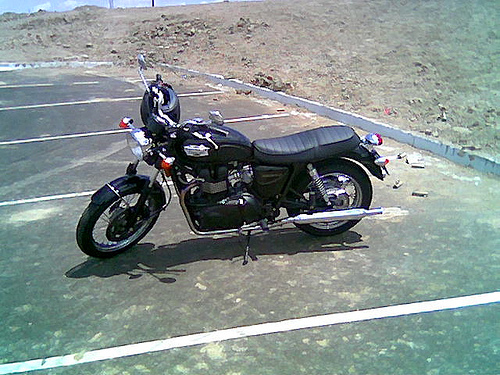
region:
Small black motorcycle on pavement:
[65, 41, 400, 284]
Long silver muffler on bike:
[283, 204, 415, 236]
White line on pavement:
[7, 331, 276, 372]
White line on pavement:
[255, 276, 461, 373]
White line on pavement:
[0, 188, 95, 212]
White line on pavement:
[3, 124, 128, 153]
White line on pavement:
[5, 101, 130, 136]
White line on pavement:
[5, 71, 127, 98]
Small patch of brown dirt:
[460, 97, 496, 155]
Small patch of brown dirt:
[394, 59, 484, 153]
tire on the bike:
[73, 172, 166, 259]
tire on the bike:
[285, 160, 375, 231]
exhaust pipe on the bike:
[197, 205, 402, 221]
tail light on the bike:
[360, 129, 384, 149]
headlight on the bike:
[120, 129, 147, 163]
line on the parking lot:
[2, 74, 173, 91]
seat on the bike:
[247, 120, 357, 157]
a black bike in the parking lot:
[70, 53, 393, 258]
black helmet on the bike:
[137, 79, 184, 129]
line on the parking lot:
[0, 283, 499, 358]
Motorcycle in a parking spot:
[65, 80, 402, 260]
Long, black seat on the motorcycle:
[221, 120, 371, 155]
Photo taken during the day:
[12, 5, 488, 355]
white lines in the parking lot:
[0, 47, 480, 322]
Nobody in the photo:
[15, 11, 487, 361]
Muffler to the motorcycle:
[275, 205, 395, 225]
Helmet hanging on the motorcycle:
[121, 75, 191, 130]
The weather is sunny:
[9, 7, 487, 369]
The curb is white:
[177, 58, 494, 173]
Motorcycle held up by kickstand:
[237, 220, 264, 271]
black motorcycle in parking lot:
[65, 65, 392, 268]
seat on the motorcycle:
[265, 125, 351, 152]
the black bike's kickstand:
[237, 230, 247, 261]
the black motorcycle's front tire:
[71, 174, 163, 257]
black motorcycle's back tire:
[296, 168, 375, 232]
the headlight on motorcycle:
[128, 130, 152, 164]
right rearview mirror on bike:
[131, 50, 157, 74]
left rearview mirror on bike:
[204, 107, 227, 127]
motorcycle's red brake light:
[366, 128, 386, 148]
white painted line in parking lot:
[181, 290, 497, 347]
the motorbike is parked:
[65, 57, 397, 287]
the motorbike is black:
[57, 40, 421, 295]